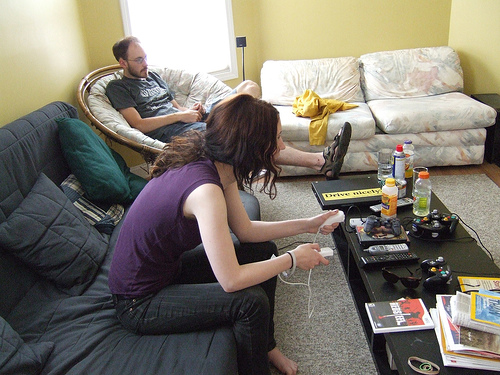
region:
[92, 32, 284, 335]
Couple lounging in living room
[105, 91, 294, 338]
Woman sitting on blue couch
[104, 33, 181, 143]
Man sitting in wicker chair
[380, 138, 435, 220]
Multiple bottles on coffee table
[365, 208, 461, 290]
Game controllers on coffee table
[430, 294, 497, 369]
Stack of magazines on coffee table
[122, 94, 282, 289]
Woman wearing purple shirt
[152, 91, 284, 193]
Woman with brown hair in ponytail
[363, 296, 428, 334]
Red and black case for Wii game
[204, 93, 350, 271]
Woman holding white controllers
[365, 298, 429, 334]
Red and black game case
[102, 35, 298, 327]
Couple lounging in den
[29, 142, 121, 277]
Multiple throw pillows on couch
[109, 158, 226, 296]
purple cotton sleeveless tank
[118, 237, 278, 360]
black color denim jeans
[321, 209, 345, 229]
white video game remote control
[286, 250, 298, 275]
white and black band on wrist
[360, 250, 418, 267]
black remote control on table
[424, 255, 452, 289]
black video game remote control on table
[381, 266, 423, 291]
sun glasses on table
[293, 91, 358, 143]
yellow sweat shirt on sofa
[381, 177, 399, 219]
juice bottle on table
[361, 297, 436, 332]
game box on table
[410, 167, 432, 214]
bottle sits on coffee table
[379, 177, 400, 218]
bottle sits on coffee table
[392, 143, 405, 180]
WD-40 sits on coffee table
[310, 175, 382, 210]
laptop sits on coffee table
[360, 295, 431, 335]
case sits on coffee table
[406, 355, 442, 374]
rubber bands sit on coffee table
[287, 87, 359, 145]
blanket sits on sofa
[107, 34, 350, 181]
man sits in chair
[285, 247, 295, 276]
bracelet is worn on wrist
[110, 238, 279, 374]
jeans are worn by woman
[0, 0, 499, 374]
the interior of a living room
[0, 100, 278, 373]
a gray couch against a wall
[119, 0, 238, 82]
a window on the wall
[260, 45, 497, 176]
a love seat against the wall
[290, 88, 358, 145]
a piece of yellow clothing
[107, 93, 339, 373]
a girl playing video games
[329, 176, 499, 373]
a black coffee table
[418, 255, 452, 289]
a video game controller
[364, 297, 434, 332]
a video game box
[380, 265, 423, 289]
a pair of sunglasses